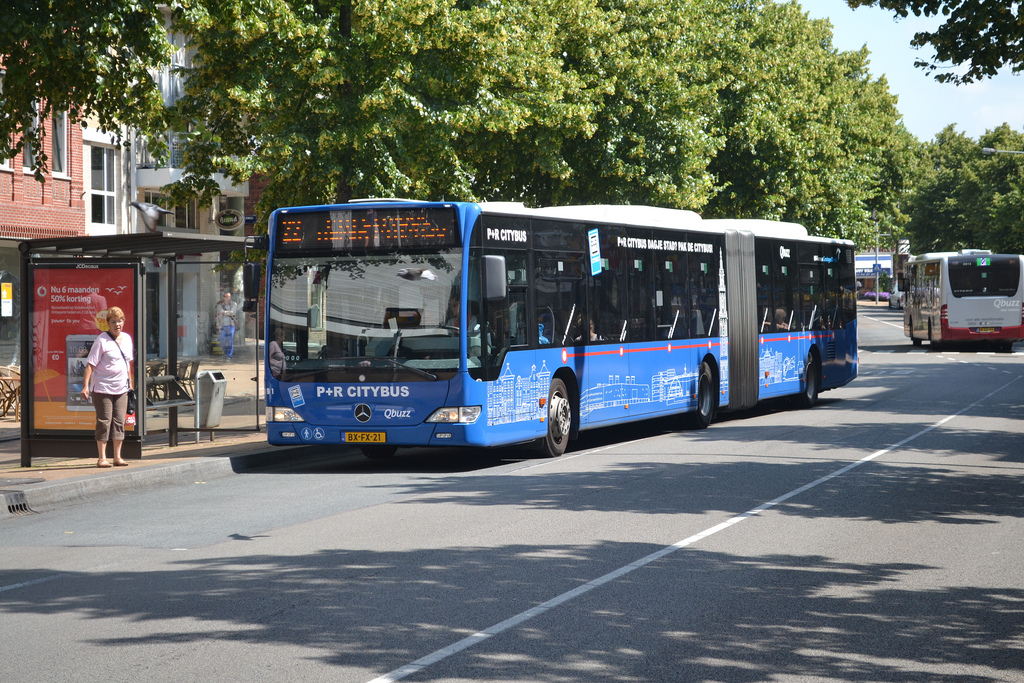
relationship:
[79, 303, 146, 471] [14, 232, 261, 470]
woman in bus stop